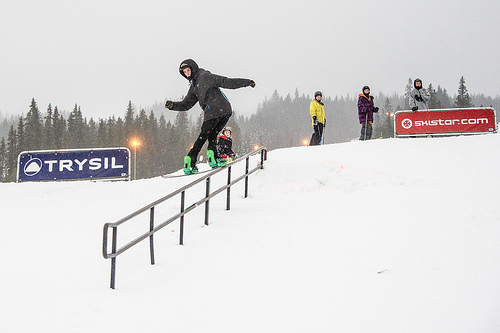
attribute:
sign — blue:
[14, 145, 131, 182]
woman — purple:
[147, 57, 258, 177]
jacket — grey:
[160, 69, 255, 130]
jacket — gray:
[410, 73, 437, 110]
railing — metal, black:
[102, 145, 268, 288]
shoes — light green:
[180, 146, 220, 171]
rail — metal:
[102, 139, 269, 287]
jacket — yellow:
[305, 98, 327, 126]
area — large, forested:
[2, 77, 494, 176]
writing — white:
[44, 155, 126, 172]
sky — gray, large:
[2, 2, 498, 102]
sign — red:
[389, 100, 498, 150]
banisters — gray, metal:
[102, 137, 274, 302]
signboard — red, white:
[389, 105, 495, 137]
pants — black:
[190, 120, 222, 160]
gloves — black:
[231, 67, 278, 99]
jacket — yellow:
[310, 100, 330, 125]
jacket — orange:
[356, 93, 371, 123]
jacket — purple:
[360, 95, 371, 119]